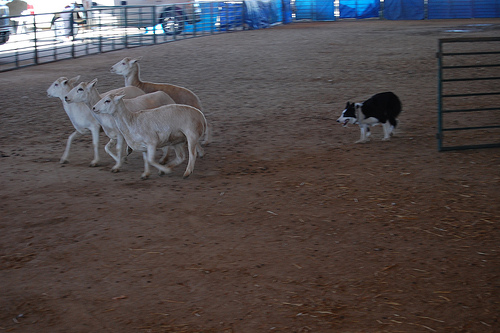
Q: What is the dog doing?
A: Herding.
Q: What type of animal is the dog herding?
A: Sheep.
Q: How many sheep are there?
A: 4.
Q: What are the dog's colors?
A: Black and white.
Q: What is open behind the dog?
A: A gate.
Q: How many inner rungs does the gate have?
A: 6.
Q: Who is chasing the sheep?
A: The dog.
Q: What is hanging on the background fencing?
A: Blue tarps.